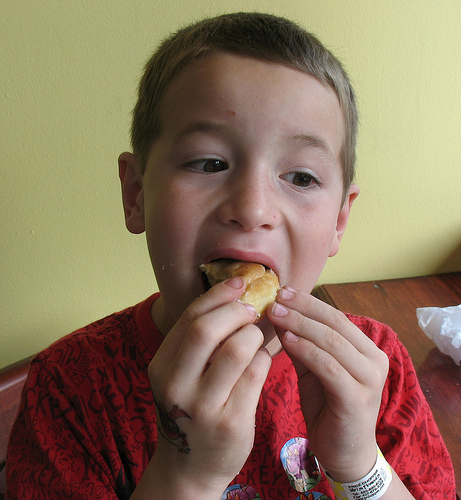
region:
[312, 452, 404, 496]
A wrist tag with letters.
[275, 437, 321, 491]
a sticker placed on a shirt.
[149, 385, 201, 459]
artwork drawn on a hand.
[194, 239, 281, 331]
delicious food being stuffed in mouth.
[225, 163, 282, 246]
the nose of a person.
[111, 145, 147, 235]
the ear of a person.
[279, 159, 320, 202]
a brown eye of a person.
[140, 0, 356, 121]
The top of a boy's head.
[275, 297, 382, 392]
fingers of a boy's left hand.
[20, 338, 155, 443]
piece of a red shirt with lettering.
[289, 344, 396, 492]
the kid is wearing a bracelet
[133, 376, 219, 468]
the kid has fake tattoo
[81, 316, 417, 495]
the shirt is white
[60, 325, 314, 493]
the kid is wearing a shirt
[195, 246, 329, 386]
the kid is eating the bread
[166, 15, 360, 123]
the kid has brown hair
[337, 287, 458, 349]
the table is brown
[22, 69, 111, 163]
the wall is yellow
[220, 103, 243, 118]
a scratch on boy's forehead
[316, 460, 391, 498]
the bracelet is printed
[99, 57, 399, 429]
The boy is eating.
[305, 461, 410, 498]
The boy has a hospital band on his wrist.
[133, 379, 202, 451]
The boy has a tattoo on his hand.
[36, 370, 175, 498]
The boy is wearing a red Mickey Mouse shirt.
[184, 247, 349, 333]
The boy is eating a doughnut.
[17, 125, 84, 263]
The wall is yellow.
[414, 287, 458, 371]
There is a white bag on the table.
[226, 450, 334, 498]
There are stickers on the shirt.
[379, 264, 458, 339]
The table is made of wood.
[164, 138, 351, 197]
The boy has brown eyes.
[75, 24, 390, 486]
boy eating piece of bread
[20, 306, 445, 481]
red shirt with darker red letters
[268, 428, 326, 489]
sticker on the front of shirt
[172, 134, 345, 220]
eyes looking toward the side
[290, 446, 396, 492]
yellow band with small print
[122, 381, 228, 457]
tattoo on the back of hand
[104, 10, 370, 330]
short brown hair and eyebrows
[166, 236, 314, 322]
mouth open wide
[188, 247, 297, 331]
fingers supporting and pushing food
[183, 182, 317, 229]
light freckles across nose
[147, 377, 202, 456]
removable tattoo on boys hand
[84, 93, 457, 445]
young boy eating a donut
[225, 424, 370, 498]
round stickers on boys red shirt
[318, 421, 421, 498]
hospital bracelet around boys left wrist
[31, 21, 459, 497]
young boy wearing a red t-shirt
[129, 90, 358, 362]
young boy with brown eyes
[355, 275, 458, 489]
brown table next to boy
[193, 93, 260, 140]
small cut on boys forehead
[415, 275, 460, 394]
white plastic bag on table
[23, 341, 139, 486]
red mickey mouse t-shirt